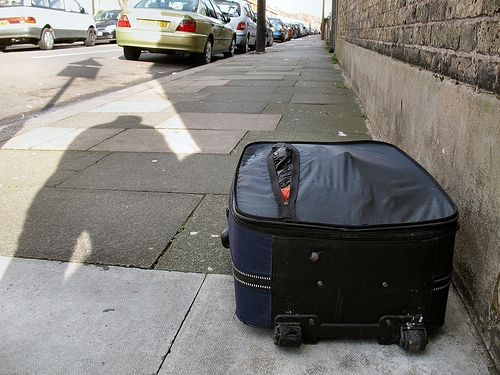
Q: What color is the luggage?
A: Blue.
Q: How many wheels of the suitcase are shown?
A: 2.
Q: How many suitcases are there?
A: 1.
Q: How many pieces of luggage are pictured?
A: 1.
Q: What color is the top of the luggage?
A: Gray.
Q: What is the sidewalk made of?
A: Concrete.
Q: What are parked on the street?
A: Cars.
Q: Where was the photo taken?
A: A sidewalk.